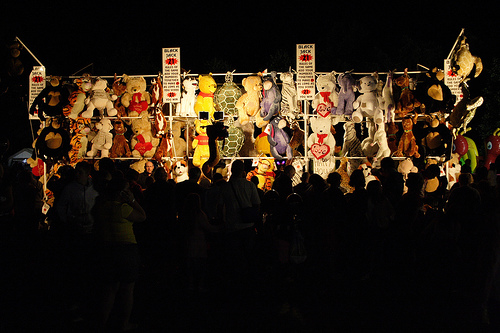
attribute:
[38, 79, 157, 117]
animals — stuffed, hanging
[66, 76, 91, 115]
tiger — stuffed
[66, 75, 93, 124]
tigger doll — red, black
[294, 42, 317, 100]
sign — white, hanging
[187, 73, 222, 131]
doll — winnie the pooh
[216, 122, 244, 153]
turtle — green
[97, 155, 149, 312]
woman — wearing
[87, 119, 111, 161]
plush — brown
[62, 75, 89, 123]
tigger — hanging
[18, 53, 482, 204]
animals — hanging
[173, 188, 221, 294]
little girl — looking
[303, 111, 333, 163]
bear — white, teddy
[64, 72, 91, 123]
tiger — hanging, stuffed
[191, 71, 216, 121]
stuffed animal — hanging up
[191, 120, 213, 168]
yellow bear — wearing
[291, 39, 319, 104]
sign — white, orange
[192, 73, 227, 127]
teddy bear — stuffed, hanging up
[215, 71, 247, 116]
turtle doll — green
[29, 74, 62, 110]
shape — like monkey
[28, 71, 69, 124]
animal — stuffed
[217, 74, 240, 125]
animal — stuffed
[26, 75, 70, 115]
monkey — brown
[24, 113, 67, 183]
monkey — brown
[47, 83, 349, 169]
animals — stuffed